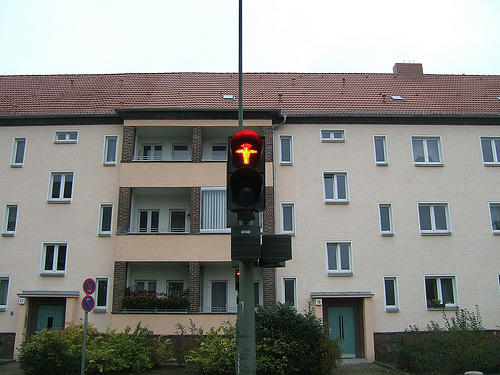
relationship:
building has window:
[0, 67, 497, 366] [423, 274, 463, 311]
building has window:
[0, 67, 497, 366] [324, 236, 358, 276]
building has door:
[0, 67, 497, 366] [324, 305, 358, 362]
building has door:
[0, 67, 497, 366] [34, 302, 66, 362]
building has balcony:
[0, 67, 497, 366] [118, 122, 278, 188]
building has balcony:
[0, 67, 497, 366] [111, 188, 280, 264]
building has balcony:
[0, 67, 497, 366] [108, 261, 283, 335]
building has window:
[0, 67, 497, 366] [323, 169, 351, 206]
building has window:
[0, 67, 497, 366] [418, 203, 455, 239]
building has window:
[0, 67, 497, 366] [411, 134, 445, 169]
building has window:
[0, 67, 497, 366] [45, 168, 76, 204]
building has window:
[0, 67, 497, 366] [39, 239, 70, 276]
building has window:
[0, 67, 497, 366] [480, 134, 499, 170]